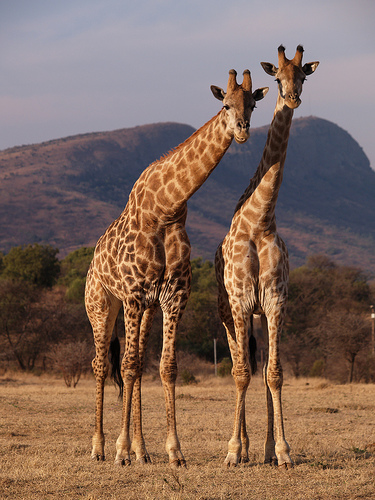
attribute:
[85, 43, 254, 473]
giraffe — tall, brown, white, leaning, spotted, large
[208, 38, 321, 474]
giraffe — tall, brown, white, spotted, large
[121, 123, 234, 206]
neck — long, spotty, yellow, bent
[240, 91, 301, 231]
neck — long, spotty, yellow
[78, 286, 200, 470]
legs — long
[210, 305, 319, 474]
legs — long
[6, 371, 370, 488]
grass — dry, brown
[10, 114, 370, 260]
hill — in background, in distance, tall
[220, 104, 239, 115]
eye — open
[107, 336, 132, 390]
tail — black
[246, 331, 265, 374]
tail — black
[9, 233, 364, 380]
trees — small, brown, leaveless, green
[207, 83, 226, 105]
ear — pointed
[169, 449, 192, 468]
hoof — large, brown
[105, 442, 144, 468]
hoof — large, brown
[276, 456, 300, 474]
hoof — large, brown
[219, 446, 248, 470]
hoof — large, brown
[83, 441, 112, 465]
hoof — large, brown, grey brown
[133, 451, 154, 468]
hoof — large, brown